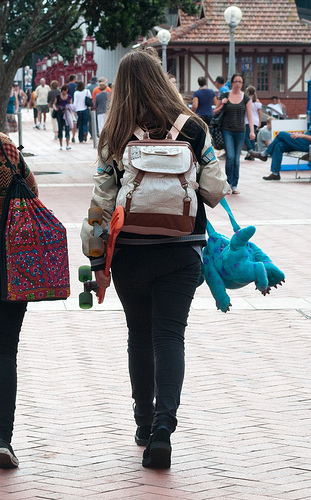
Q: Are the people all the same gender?
A: No, they are both male and female.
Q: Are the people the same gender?
A: No, they are both male and female.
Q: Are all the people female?
A: No, they are both male and female.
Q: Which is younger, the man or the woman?
A: The woman is younger than the man.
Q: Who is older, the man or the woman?
A: The man is older than the woman.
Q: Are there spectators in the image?
A: No, there are no spectators.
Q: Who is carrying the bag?
A: The girl is carrying the bag.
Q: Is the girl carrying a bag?
A: Yes, the girl is carrying a bag.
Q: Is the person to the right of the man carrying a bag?
A: Yes, the girl is carrying a bag.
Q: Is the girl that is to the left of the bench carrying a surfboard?
A: No, the girl is carrying a bag.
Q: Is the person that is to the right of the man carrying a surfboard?
A: No, the girl is carrying a bag.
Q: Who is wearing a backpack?
A: The girl is wearing a backpack.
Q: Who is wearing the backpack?
A: The girl is wearing a backpack.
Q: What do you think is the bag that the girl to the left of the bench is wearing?
A: The bag is a backpack.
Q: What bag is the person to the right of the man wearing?
A: The girl is wearing a backpack.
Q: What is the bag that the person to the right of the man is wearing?
A: The bag is a backpack.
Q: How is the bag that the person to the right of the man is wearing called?
A: The bag is a backpack.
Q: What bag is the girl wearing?
A: The girl is wearing a backpack.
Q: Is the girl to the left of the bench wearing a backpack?
A: Yes, the girl is wearing a backpack.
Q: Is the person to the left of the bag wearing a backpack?
A: Yes, the girl is wearing a backpack.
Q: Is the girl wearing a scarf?
A: No, the girl is wearing a backpack.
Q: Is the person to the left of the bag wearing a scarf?
A: No, the girl is wearing a backpack.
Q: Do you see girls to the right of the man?
A: Yes, there is a girl to the right of the man.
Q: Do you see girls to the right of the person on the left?
A: Yes, there is a girl to the right of the man.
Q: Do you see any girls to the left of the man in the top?
A: No, the girl is to the right of the man.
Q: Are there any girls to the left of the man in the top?
A: No, the girl is to the right of the man.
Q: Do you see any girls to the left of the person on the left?
A: No, the girl is to the right of the man.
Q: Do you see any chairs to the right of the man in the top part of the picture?
A: No, there is a girl to the right of the man.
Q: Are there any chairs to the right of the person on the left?
A: No, there is a girl to the right of the man.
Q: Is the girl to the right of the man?
A: Yes, the girl is to the right of the man.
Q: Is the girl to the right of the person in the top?
A: Yes, the girl is to the right of the man.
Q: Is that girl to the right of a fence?
A: No, the girl is to the right of the man.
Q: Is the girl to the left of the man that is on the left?
A: No, the girl is to the right of the man.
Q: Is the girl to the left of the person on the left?
A: No, the girl is to the right of the man.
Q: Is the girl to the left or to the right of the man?
A: The girl is to the right of the man.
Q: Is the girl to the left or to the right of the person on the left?
A: The girl is to the right of the man.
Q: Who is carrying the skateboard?
A: The girl is carrying the skateboard.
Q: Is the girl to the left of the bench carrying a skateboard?
A: Yes, the girl is carrying a skateboard.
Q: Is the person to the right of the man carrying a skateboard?
A: Yes, the girl is carrying a skateboard.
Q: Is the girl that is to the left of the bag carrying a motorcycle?
A: No, the girl is carrying a skateboard.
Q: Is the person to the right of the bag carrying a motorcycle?
A: No, the girl is carrying a skateboard.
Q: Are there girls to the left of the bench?
A: Yes, there is a girl to the left of the bench.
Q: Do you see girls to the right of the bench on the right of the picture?
A: No, the girl is to the left of the bench.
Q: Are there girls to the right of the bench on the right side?
A: No, the girl is to the left of the bench.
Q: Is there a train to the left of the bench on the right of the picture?
A: No, there is a girl to the left of the bench.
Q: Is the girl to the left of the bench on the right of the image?
A: Yes, the girl is to the left of the bench.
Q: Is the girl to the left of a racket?
A: No, the girl is to the left of the bench.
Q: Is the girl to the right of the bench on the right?
A: No, the girl is to the left of the bench.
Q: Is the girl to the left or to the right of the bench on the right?
A: The girl is to the left of the bench.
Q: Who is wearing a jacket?
A: The girl is wearing a jacket.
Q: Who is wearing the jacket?
A: The girl is wearing a jacket.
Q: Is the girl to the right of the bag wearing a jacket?
A: Yes, the girl is wearing a jacket.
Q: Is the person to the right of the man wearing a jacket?
A: Yes, the girl is wearing a jacket.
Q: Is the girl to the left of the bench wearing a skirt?
A: No, the girl is wearing a jacket.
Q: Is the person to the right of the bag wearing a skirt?
A: No, the girl is wearing a jacket.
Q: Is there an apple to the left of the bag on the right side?
A: No, there is a girl to the left of the bag.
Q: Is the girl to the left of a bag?
A: Yes, the girl is to the left of a bag.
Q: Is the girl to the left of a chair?
A: No, the girl is to the left of a bag.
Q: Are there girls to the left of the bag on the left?
A: No, the girl is to the right of the bag.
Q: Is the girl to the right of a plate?
A: No, the girl is to the right of the bag.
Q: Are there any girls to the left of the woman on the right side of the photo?
A: Yes, there is a girl to the left of the woman.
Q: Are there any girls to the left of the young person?
A: Yes, there is a girl to the left of the woman.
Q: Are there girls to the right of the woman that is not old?
A: No, the girl is to the left of the woman.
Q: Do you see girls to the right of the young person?
A: No, the girl is to the left of the woman.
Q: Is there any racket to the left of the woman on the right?
A: No, there is a girl to the left of the woman.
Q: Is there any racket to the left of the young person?
A: No, there is a girl to the left of the woman.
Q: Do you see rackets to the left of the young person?
A: No, there is a girl to the left of the woman.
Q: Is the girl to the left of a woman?
A: Yes, the girl is to the left of a woman.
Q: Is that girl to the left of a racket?
A: No, the girl is to the left of a woman.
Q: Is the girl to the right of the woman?
A: No, the girl is to the left of the woman.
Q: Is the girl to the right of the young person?
A: No, the girl is to the left of the woman.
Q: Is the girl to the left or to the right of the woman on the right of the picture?
A: The girl is to the left of the woman.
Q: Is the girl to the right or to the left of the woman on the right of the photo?
A: The girl is to the left of the woman.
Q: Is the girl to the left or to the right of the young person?
A: The girl is to the left of the woman.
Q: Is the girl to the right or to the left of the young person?
A: The girl is to the left of the woman.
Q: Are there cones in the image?
A: No, there are no cones.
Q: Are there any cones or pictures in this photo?
A: No, there are no cones or pictures.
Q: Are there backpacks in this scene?
A: Yes, there is a backpack.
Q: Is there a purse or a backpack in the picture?
A: Yes, there is a backpack.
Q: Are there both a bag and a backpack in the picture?
A: Yes, there are both a backpack and a bag.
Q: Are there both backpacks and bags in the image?
A: Yes, there are both a backpack and a bag.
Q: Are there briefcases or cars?
A: No, there are no cars or briefcases.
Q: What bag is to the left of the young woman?
A: The bag is a backpack.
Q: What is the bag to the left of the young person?
A: The bag is a backpack.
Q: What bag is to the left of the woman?
A: The bag is a backpack.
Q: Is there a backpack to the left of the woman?
A: Yes, there is a backpack to the left of the woman.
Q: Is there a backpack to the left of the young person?
A: Yes, there is a backpack to the left of the woman.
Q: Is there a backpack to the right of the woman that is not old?
A: No, the backpack is to the left of the woman.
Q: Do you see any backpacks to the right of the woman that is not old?
A: No, the backpack is to the left of the woman.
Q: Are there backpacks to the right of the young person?
A: No, the backpack is to the left of the woman.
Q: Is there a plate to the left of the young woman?
A: No, there is a backpack to the left of the woman.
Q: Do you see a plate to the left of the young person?
A: No, there is a backpack to the left of the woman.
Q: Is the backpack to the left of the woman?
A: Yes, the backpack is to the left of the woman.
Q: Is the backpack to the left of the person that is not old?
A: Yes, the backpack is to the left of the woman.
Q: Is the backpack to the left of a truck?
A: No, the backpack is to the left of the woman.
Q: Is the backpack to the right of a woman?
A: No, the backpack is to the left of a woman.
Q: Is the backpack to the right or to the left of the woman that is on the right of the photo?
A: The backpack is to the left of the woman.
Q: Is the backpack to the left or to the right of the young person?
A: The backpack is to the left of the woman.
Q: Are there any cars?
A: No, there are no cars.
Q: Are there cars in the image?
A: No, there are no cars.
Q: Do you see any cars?
A: No, there are no cars.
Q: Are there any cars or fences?
A: No, there are no cars or fences.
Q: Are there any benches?
A: Yes, there is a bench.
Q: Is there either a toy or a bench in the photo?
A: Yes, there is a bench.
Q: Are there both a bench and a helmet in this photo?
A: No, there is a bench but no helmets.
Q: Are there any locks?
A: No, there are no locks.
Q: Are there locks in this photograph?
A: No, there are no locks.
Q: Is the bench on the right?
A: Yes, the bench is on the right of the image.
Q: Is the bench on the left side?
A: No, the bench is on the right of the image.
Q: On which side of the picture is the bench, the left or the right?
A: The bench is on the right of the image.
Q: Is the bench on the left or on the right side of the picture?
A: The bench is on the right of the image.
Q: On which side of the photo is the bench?
A: The bench is on the right of the image.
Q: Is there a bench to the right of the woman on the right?
A: Yes, there is a bench to the right of the woman.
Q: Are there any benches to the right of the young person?
A: Yes, there is a bench to the right of the woman.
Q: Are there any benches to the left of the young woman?
A: No, the bench is to the right of the woman.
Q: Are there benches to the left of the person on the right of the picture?
A: No, the bench is to the right of the woman.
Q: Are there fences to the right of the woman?
A: No, there is a bench to the right of the woman.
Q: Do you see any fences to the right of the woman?
A: No, there is a bench to the right of the woman.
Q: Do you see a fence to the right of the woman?
A: No, there is a bench to the right of the woman.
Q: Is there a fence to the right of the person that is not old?
A: No, there is a bench to the right of the woman.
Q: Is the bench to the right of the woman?
A: Yes, the bench is to the right of the woman.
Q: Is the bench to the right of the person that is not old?
A: Yes, the bench is to the right of the woman.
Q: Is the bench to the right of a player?
A: No, the bench is to the right of the woman.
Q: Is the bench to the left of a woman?
A: No, the bench is to the right of a woman.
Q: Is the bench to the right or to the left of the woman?
A: The bench is to the right of the woman.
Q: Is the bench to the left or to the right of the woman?
A: The bench is to the right of the woman.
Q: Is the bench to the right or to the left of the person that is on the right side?
A: The bench is to the right of the woman.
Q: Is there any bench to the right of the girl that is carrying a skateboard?
A: Yes, there is a bench to the right of the girl.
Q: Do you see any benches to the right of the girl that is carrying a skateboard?
A: Yes, there is a bench to the right of the girl.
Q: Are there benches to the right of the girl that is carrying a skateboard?
A: Yes, there is a bench to the right of the girl.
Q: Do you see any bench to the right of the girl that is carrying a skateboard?
A: Yes, there is a bench to the right of the girl.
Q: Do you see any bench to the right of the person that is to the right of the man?
A: Yes, there is a bench to the right of the girl.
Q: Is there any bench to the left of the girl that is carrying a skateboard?
A: No, the bench is to the right of the girl.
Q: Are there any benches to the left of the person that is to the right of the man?
A: No, the bench is to the right of the girl.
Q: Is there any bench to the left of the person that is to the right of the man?
A: No, the bench is to the right of the girl.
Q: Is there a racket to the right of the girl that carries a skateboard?
A: No, there is a bench to the right of the girl.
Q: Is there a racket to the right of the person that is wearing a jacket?
A: No, there is a bench to the right of the girl.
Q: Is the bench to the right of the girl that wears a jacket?
A: Yes, the bench is to the right of the girl.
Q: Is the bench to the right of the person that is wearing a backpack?
A: Yes, the bench is to the right of the girl.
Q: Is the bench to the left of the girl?
A: No, the bench is to the right of the girl.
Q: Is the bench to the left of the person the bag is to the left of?
A: No, the bench is to the right of the girl.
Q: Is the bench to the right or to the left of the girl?
A: The bench is to the right of the girl.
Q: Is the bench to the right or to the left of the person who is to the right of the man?
A: The bench is to the right of the girl.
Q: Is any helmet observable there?
A: No, there are no helmets.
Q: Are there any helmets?
A: No, there are no helmets.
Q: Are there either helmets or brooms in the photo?
A: No, there are no helmets or brooms.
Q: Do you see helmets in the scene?
A: No, there are no helmets.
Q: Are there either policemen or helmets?
A: No, there are no helmets or policemen.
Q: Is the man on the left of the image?
A: Yes, the man is on the left of the image.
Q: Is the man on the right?
A: No, the man is on the left of the image.